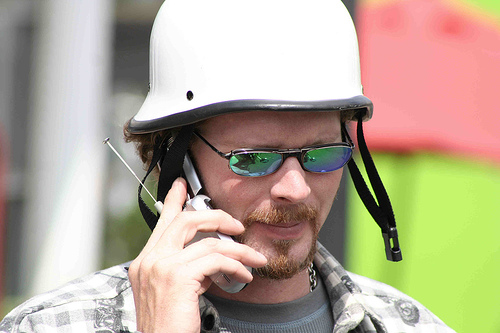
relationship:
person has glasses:
[1, 1, 458, 333] [193, 122, 356, 177]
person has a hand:
[1, 1, 458, 333] [127, 177, 268, 333]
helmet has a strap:
[126, 0, 373, 135] [341, 116, 403, 262]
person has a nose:
[1, 1, 458, 333] [270, 170, 312, 205]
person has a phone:
[1, 1, 458, 333] [102, 136, 253, 294]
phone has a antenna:
[102, 136, 253, 294] [102, 136, 157, 204]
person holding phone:
[1, 1, 458, 333] [102, 136, 253, 294]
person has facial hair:
[1, 1, 458, 333] [235, 204, 317, 280]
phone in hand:
[102, 136, 253, 294] [127, 177, 268, 333]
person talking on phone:
[1, 1, 458, 333] [102, 136, 253, 294]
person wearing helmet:
[1, 1, 458, 333] [126, 0, 373, 135]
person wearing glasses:
[1, 1, 458, 333] [193, 122, 356, 177]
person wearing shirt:
[1, 1, 458, 333] [0, 238, 457, 332]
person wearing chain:
[1, 1, 458, 333] [309, 263, 318, 292]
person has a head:
[1, 1, 458, 333] [177, 110, 344, 281]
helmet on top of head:
[126, 0, 373, 135] [177, 110, 344, 281]